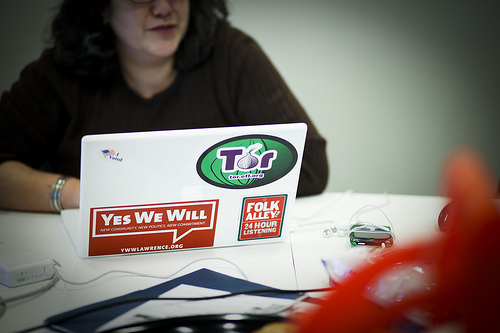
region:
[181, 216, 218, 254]
aprt of a line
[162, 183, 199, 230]
aprt of a lien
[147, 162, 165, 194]
aprt f a box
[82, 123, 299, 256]
stickers on lap top cover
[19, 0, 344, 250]
woman working on lap top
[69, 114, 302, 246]
white lap top computer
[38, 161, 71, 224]
silver bracelets on woman's wrists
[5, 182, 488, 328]
woman working at white table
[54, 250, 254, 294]
white wire on white table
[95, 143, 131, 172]
I voted sticker with american flag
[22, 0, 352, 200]
woman wearing a brown shirt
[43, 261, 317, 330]
blue booklet on table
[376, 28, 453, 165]
walls painted solid white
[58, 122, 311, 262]
Woman on a laptop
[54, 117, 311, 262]
Woman is on a laptop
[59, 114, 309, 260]
Woman on a white laptop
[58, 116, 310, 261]
Woman is on a white laptop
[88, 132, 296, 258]
Stickers on laptop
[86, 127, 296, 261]
Stickers are on laptop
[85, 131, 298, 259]
Stickers on back of laptop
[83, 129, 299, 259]
Stickers are on back of laptop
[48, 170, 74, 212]
Woman is wearing a bracelet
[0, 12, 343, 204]
Woman is wearing a brown shirt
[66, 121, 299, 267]
stickers covering the top of white computer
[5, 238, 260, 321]
white power cord for the laptop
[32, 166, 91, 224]
silver cuff bracelet on right wrist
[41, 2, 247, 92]
woman has medium length dark hair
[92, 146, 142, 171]
I Voted sticker with American flag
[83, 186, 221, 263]
Orange and white sticker that says Yes We Will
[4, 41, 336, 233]
dark brown textured long sleeved shirt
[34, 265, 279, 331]
dark blue folder with papers inside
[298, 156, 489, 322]
shiny orange item on the white desk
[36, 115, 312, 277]
white laptop on clean white desk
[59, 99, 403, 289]
a white macbook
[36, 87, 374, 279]
a white apple laptop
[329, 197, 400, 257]
an iPhone with the headphones wrapped around it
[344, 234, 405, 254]
a black iPhone 3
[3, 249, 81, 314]
the white power brick to a macbook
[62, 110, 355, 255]
there are stickers on the computer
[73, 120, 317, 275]
stickers on a macbook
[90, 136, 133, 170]
an "I Voted" sticker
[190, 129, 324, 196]
a green Tor sticker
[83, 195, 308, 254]
these stickers are both red